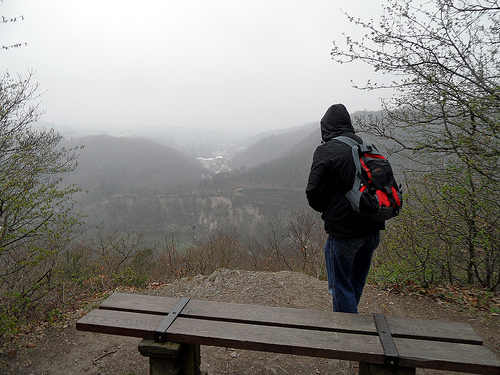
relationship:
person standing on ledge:
[305, 103, 401, 314] [117, 268, 496, 330]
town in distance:
[198, 145, 241, 179] [0, 0, 496, 232]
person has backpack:
[305, 103, 401, 314] [347, 142, 402, 219]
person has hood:
[305, 103, 401, 314] [320, 103, 362, 139]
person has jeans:
[305, 103, 401, 314] [323, 229, 382, 313]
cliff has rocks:
[112, 267, 500, 327] [172, 271, 204, 283]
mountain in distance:
[31, 132, 224, 198] [0, 0, 496, 232]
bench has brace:
[75, 290, 495, 374] [153, 295, 189, 341]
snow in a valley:
[200, 192, 231, 210] [138, 122, 310, 276]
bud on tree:
[20, 13, 24, 22] [0, 11, 122, 374]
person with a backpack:
[305, 103, 401, 314] [347, 142, 402, 219]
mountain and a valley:
[31, 132, 224, 198] [138, 122, 310, 276]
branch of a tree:
[25, 69, 35, 89] [0, 11, 122, 374]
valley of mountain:
[138, 122, 310, 276] [31, 132, 224, 198]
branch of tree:
[25, 69, 35, 89] [0, 11, 122, 374]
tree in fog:
[0, 11, 122, 374] [2, 2, 493, 305]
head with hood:
[320, 112, 353, 141] [320, 103, 362, 139]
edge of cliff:
[213, 266, 299, 274] [112, 267, 500, 327]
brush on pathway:
[368, 196, 438, 291] [0, 268, 498, 372]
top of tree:
[0, 11, 80, 169] [0, 11, 122, 374]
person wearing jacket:
[305, 103, 401, 314] [304, 103, 403, 235]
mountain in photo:
[31, 132, 224, 198] [1, 1, 498, 374]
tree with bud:
[0, 11, 122, 374] [20, 13, 24, 22]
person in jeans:
[305, 103, 401, 314] [323, 229, 382, 313]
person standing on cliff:
[305, 103, 401, 314] [112, 267, 500, 327]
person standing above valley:
[305, 103, 401, 314] [138, 122, 310, 276]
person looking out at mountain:
[305, 103, 401, 314] [31, 132, 224, 198]